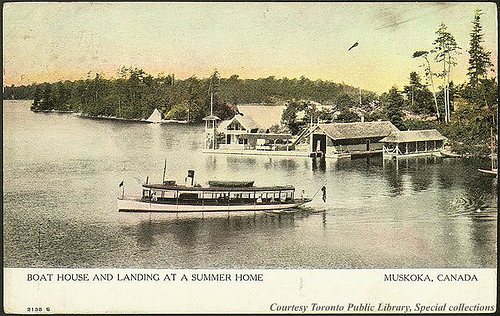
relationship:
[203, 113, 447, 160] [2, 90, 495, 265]
buildings overlooking water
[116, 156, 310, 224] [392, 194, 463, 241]
boat in water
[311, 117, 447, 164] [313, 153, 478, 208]
boathouses on water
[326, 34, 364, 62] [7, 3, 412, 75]
bird flying in sky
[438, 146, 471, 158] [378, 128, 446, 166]
boat by dock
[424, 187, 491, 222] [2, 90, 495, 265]
ripples in water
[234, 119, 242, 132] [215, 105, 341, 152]
window on buildings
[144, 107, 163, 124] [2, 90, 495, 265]
sailboat in water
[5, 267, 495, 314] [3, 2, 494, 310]
black lettering on card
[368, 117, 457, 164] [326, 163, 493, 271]
dock next to lake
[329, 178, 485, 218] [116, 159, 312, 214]
water from wake of boat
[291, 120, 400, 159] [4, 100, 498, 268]
boathouses next to lake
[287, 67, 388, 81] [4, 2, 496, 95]
light in sky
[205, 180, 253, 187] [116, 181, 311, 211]
rowboat on top of boat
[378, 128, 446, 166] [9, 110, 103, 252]
dock on river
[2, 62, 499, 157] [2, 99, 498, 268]
woods along lake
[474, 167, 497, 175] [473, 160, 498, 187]
edge of boat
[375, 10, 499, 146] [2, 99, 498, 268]
trees by lake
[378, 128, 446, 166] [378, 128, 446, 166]
dock a dock